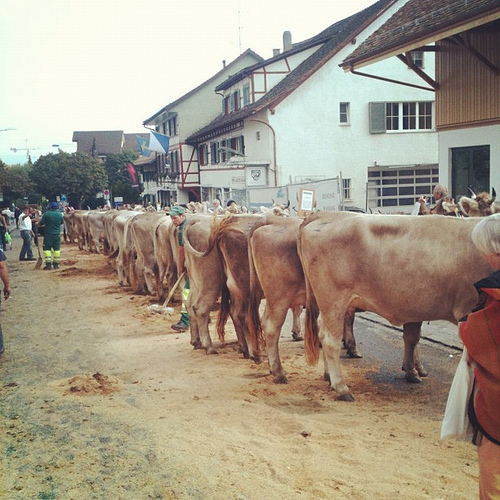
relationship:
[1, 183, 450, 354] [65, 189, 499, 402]
people behind cows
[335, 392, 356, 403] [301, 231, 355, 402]
hoof on leg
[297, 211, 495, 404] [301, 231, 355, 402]
cow has leg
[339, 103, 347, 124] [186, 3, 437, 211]
window on home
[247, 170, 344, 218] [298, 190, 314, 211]
structure has sign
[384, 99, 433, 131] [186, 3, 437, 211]
three windows on home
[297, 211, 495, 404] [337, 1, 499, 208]
cow in front of building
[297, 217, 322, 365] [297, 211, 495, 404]
tail on cow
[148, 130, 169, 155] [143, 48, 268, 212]
flag on building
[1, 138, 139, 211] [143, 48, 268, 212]
trees outside of building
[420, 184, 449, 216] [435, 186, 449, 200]
person has hair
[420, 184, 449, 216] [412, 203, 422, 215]
person holding bag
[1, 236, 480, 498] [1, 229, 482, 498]
sand spread over pavement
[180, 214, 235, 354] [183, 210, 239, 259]
cow has tail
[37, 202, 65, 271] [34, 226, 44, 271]
person holding shovel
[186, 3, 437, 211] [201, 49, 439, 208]
home has windows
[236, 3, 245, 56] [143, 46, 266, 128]
antenna on rooftop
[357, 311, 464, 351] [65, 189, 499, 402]
sidewalk next to cows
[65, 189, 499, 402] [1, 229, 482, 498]
cows on pavement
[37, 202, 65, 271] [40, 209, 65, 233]
person wearing shirt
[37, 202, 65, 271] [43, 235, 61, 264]
person wearing pants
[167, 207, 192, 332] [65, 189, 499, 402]
man walking between cows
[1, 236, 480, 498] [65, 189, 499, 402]
sand behind cows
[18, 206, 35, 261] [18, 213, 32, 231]
man in shirt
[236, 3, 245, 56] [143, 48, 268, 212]
antenna on top of building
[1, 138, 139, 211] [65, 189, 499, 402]
trees behind cows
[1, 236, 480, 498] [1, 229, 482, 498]
sand on pavement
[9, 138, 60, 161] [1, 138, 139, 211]
crane behind trees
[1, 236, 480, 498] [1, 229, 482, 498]
sand covers pavement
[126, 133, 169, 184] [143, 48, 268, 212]
flags on side of building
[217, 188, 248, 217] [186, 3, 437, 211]
fence by home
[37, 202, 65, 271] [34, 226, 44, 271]
person has shovel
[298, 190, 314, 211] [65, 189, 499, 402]
sign in front of cows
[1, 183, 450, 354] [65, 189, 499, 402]
people wander around cows